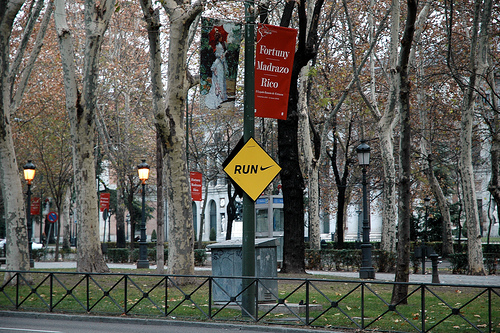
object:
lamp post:
[135, 157, 149, 268]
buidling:
[0, 73, 500, 247]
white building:
[146, 130, 380, 243]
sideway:
[308, 270, 496, 286]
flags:
[194, 15, 289, 118]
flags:
[188, 166, 203, 203]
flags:
[96, 187, 116, 217]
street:
[4, 308, 289, 331]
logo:
[257, 162, 274, 171]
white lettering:
[253, 37, 290, 99]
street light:
[23, 159, 34, 266]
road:
[10, 310, 132, 332]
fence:
[1, 269, 498, 331]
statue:
[218, 212, 227, 237]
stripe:
[0, 326, 65, 331]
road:
[0, 310, 303, 331]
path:
[36, 253, 208, 274]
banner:
[253, 14, 299, 121]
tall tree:
[139, 0, 209, 289]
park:
[1, 3, 499, 332]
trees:
[1, 2, 497, 284]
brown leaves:
[4, 0, 500, 183]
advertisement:
[221, 137, 282, 202]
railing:
[0, 268, 500, 331]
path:
[1, 315, 307, 331]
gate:
[0, 257, 497, 329]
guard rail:
[0, 269, 499, 330]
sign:
[198, 15, 238, 110]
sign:
[189, 172, 202, 199]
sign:
[197, 15, 242, 112]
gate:
[207, 276, 310, 325]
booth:
[257, 197, 282, 236]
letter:
[232, 164, 242, 174]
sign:
[224, 132, 284, 201]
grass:
[308, 271, 397, 320]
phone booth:
[250, 193, 305, 258]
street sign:
[44, 209, 60, 223]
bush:
[399, 238, 449, 265]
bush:
[341, 242, 378, 267]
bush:
[128, 244, 160, 260]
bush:
[103, 244, 130, 264]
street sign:
[209, 135, 290, 209]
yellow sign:
[221, 136, 281, 201]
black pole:
[241, 0, 256, 322]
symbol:
[259, 162, 277, 172]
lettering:
[255, 60, 291, 74]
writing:
[229, 160, 258, 176]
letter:
[240, 160, 249, 176]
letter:
[251, 162, 258, 174]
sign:
[211, 130, 289, 210]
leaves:
[16, 271, 497, 329]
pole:
[16, 169, 40, 271]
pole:
[128, 168, 151, 252]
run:
[236, 161, 260, 173]